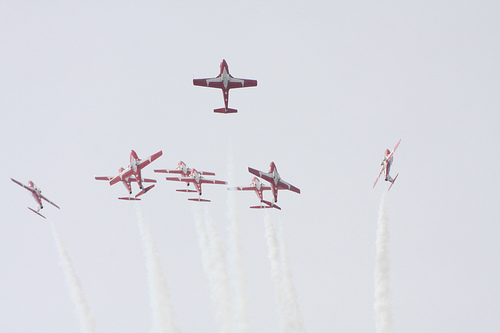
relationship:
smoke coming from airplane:
[372, 186, 394, 331] [368, 138, 401, 190]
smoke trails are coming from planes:
[42, 119, 397, 332] [365, 140, 403, 191]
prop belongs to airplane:
[219, 58, 228, 64] [191, 58, 258, 115]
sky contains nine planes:
[1, 1, 500, 330] [12, 59, 403, 223]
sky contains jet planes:
[1, 1, 500, 330] [12, 59, 403, 223]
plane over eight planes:
[191, 58, 258, 115] [11, 138, 403, 218]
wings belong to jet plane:
[193, 76, 259, 91] [191, 58, 258, 115]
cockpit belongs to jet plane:
[388, 154, 394, 165] [368, 138, 401, 190]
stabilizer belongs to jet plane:
[215, 107, 238, 116] [191, 58, 258, 115]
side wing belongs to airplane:
[192, 73, 223, 92] [191, 58, 258, 115]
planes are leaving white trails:
[12, 59, 403, 223] [42, 119, 397, 332]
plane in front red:
[191, 58, 258, 115] [197, 80, 200, 83]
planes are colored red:
[12, 59, 403, 223] [197, 80, 200, 83]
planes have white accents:
[12, 59, 403, 223] [205, 69, 244, 90]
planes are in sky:
[12, 59, 403, 223] [1, 1, 500, 330]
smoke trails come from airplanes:
[42, 119, 397, 332] [12, 59, 403, 223]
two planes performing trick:
[155, 162, 228, 204] [155, 161, 227, 207]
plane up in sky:
[191, 58, 258, 115] [1, 1, 500, 330]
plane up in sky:
[11, 177, 61, 218] [1, 1, 500, 330]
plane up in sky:
[368, 138, 401, 190] [1, 1, 500, 330]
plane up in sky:
[96, 167, 156, 204] [1, 1, 500, 330]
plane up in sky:
[155, 162, 228, 204] [1, 1, 500, 330]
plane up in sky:
[227, 176, 285, 211] [1, 1, 500, 330]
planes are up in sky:
[12, 59, 403, 223] [1, 1, 500, 330]